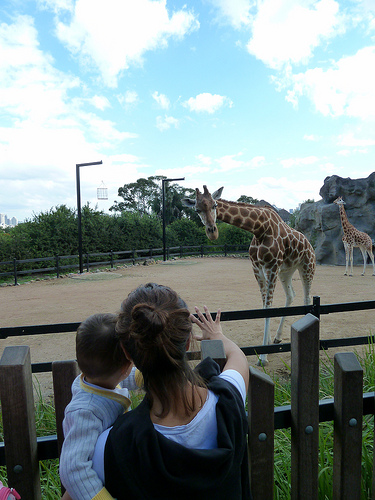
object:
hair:
[114, 281, 210, 422]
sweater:
[103, 374, 251, 500]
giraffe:
[180, 185, 316, 369]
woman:
[60, 282, 251, 498]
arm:
[60, 423, 118, 498]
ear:
[180, 197, 196, 208]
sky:
[0, 0, 374, 215]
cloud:
[188, 91, 225, 114]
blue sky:
[183, 57, 249, 91]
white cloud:
[335, 128, 374, 146]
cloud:
[52, 0, 199, 90]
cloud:
[240, 0, 345, 72]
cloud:
[79, 110, 136, 147]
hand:
[189, 305, 222, 341]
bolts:
[347, 415, 358, 427]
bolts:
[304, 420, 316, 437]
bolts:
[256, 430, 269, 442]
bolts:
[11, 462, 24, 472]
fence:
[0, 296, 375, 500]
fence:
[0, 240, 241, 285]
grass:
[319, 352, 333, 402]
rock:
[30, 279, 33, 283]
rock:
[44, 277, 48, 280]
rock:
[60, 274, 65, 279]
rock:
[17, 282, 21, 287]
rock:
[0, 282, 7, 288]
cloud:
[292, 47, 374, 123]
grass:
[274, 427, 292, 498]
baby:
[55, 311, 149, 498]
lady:
[60, 280, 250, 500]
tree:
[109, 175, 184, 261]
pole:
[76, 164, 83, 273]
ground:
[0, 254, 375, 500]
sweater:
[58, 366, 143, 499]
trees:
[0, 227, 32, 280]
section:
[12, 253, 58, 285]